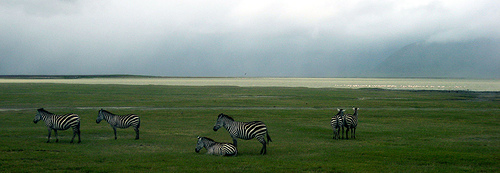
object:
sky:
[1, 0, 499, 77]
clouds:
[0, 0, 92, 19]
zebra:
[32, 108, 82, 144]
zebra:
[94, 108, 142, 141]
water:
[1, 76, 499, 91]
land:
[0, 74, 254, 79]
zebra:
[194, 135, 239, 157]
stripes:
[66, 122, 79, 130]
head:
[194, 135, 205, 153]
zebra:
[330, 108, 346, 140]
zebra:
[342, 107, 360, 140]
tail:
[265, 129, 273, 147]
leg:
[46, 127, 52, 144]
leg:
[131, 124, 140, 140]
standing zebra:
[212, 113, 273, 156]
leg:
[254, 135, 267, 155]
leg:
[337, 127, 341, 140]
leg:
[353, 127, 357, 140]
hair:
[37, 108, 54, 115]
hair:
[100, 109, 116, 116]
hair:
[202, 136, 215, 142]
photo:
[0, 0, 499, 173]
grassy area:
[1, 82, 500, 173]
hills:
[362, 34, 499, 77]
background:
[1, 1, 498, 77]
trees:
[407, 44, 422, 51]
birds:
[244, 73, 247, 76]